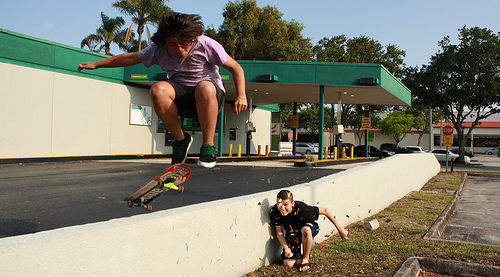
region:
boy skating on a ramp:
[67, 9, 250, 223]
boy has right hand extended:
[59, 8, 261, 180]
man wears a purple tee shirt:
[70, 6, 253, 179]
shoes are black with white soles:
[162, 131, 221, 175]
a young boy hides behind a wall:
[255, 184, 357, 275]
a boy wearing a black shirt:
[262, 183, 352, 274]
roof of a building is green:
[1, 31, 128, 76]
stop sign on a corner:
[438, 117, 457, 178]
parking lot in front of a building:
[422, 159, 497, 247]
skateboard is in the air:
[112, 153, 203, 217]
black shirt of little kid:
[287, 188, 323, 228]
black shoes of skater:
[187, 115, 224, 178]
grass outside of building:
[397, 185, 446, 267]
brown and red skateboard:
[97, 161, 192, 221]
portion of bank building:
[309, 50, 429, 115]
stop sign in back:
[425, 113, 466, 156]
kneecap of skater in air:
[143, 78, 176, 100]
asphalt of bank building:
[31, 150, 97, 225]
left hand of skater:
[222, 93, 264, 119]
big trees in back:
[413, 39, 489, 136]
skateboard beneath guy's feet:
[128, 150, 200, 209]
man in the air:
[83, 38, 245, 221]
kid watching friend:
[258, 166, 350, 256]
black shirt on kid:
[265, 192, 326, 225]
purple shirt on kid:
[123, 41, 230, 105]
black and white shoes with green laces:
[192, 123, 231, 176]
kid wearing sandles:
[293, 252, 323, 275]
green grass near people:
[398, 203, 432, 248]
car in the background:
[290, 131, 326, 168]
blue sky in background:
[360, 0, 407, 27]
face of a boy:
[283, 188, 287, 203]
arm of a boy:
[336, 220, 346, 225]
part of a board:
[155, 174, 172, 189]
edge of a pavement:
[408, 253, 423, 270]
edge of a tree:
[447, 82, 452, 101]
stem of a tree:
[461, 117, 466, 126]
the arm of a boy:
[200, 45, 252, 116]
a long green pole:
[315, 85, 325, 160]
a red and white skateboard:
[116, 160, 191, 210]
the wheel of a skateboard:
[125, 195, 135, 205]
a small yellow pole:
[235, 140, 240, 155]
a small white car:
[426, 145, 466, 160]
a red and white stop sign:
[437, 120, 457, 130]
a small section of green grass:
[420, 161, 460, 186]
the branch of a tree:
[450, 110, 465, 165]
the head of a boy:
[274, 187, 299, 216]